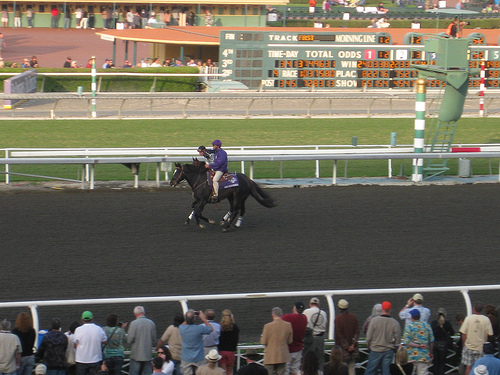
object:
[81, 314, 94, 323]
head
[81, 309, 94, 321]
green hat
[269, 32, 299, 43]
letter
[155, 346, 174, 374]
woman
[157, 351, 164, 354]
glasses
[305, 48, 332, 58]
letter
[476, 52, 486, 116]
pole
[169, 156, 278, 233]
horse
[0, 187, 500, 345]
track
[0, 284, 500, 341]
barricade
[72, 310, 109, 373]
man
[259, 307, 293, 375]
man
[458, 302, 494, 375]
man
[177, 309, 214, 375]
man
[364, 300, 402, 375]
man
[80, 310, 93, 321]
cap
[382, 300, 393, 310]
cap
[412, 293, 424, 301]
cap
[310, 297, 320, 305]
cap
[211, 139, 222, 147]
cap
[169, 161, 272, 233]
horse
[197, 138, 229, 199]
man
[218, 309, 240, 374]
woman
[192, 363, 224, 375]
shirt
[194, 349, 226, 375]
man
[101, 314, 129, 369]
woman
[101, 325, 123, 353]
crossbody bag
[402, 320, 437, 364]
shirt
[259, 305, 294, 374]
gentleman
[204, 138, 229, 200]
gentleman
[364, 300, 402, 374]
gentleman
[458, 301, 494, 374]
gentleman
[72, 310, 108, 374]
gentleman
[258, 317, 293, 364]
tan coat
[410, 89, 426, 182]
green/white pole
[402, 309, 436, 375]
man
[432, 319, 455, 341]
shirt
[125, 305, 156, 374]
man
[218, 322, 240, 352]
shirt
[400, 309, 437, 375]
someone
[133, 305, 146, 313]
hair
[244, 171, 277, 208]
tail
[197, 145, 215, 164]
hoodie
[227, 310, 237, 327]
ponytail